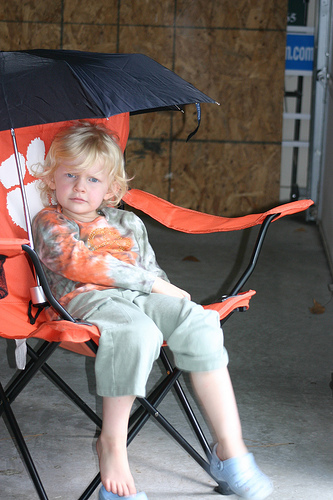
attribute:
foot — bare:
[93, 437, 137, 497]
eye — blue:
[89, 174, 100, 184]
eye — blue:
[64, 171, 77, 180]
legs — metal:
[0, 341, 235, 499]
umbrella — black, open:
[6, 36, 223, 245]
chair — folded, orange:
[0, 86, 294, 448]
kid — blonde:
[21, 113, 229, 362]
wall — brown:
[156, 67, 186, 96]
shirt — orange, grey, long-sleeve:
[24, 203, 172, 322]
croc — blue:
[99, 481, 145, 498]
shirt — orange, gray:
[27, 204, 195, 322]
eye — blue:
[87, 177, 99, 185]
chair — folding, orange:
[0, 111, 313, 498]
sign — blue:
[280, 26, 321, 67]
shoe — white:
[211, 454, 268, 497]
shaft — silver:
[8, 128, 48, 305]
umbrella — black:
[0, 50, 220, 324]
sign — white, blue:
[277, 25, 332, 84]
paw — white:
[2, 149, 58, 218]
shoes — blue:
[93, 443, 269, 496]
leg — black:
[59, 337, 234, 495]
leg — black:
[0, 368, 184, 498]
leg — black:
[17, 336, 103, 431]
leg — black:
[7, 339, 60, 411]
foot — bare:
[90, 426, 142, 498]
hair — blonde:
[37, 115, 133, 219]